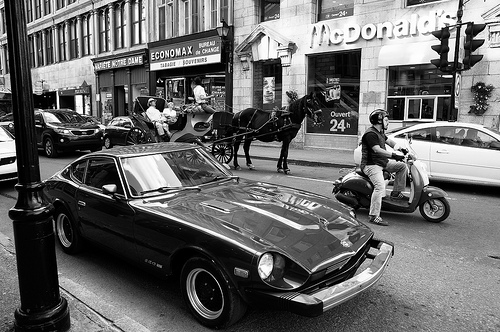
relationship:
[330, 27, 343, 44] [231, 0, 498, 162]
letter on building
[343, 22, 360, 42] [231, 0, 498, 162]
letter on building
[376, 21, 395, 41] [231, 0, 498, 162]
letter on building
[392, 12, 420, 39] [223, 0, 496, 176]
letter on building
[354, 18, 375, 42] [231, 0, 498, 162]
letter on building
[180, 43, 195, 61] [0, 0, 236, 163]
letter on building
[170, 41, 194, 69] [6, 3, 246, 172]
letter on building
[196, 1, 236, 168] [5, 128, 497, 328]
street lamp on road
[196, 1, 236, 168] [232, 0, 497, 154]
street lamp near mcdonalds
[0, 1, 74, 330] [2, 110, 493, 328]
streetlamp on street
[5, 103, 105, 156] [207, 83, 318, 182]
truck behind horse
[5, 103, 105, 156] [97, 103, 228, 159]
truck behind buggy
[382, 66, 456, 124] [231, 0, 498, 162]
windows are in front of building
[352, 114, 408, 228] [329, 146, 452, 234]
man on scooter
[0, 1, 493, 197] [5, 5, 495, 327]
stores are on city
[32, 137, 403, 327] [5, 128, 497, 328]
corvet driving down road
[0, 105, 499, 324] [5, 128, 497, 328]
vehicles are driving down road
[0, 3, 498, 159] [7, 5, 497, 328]
buildings are lining in street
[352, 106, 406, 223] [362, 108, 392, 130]
man wearing helmet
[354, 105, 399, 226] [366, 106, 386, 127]
man wearing helmet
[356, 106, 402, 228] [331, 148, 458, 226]
man riding an scooter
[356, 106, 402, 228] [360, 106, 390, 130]
man wearing helmet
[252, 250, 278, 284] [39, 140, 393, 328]
headlight on car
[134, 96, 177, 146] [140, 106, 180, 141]
man wearing shirt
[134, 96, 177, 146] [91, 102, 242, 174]
man riding a buggy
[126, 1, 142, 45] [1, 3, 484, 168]
window pane on building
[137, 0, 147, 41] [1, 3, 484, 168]
window pane on building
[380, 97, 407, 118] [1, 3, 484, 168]
window pane on building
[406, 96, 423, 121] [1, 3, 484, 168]
window pane on building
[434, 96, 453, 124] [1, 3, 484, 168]
window pane on building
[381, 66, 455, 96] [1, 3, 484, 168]
window pane on building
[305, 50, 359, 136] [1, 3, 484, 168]
window pane on building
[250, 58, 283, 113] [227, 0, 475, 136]
window pane in city building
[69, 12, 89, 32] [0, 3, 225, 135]
window pane in city building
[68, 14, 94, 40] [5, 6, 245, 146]
window pane in city building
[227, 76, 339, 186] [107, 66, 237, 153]
horse pulling carraige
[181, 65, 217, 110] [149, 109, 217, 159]
person in carraige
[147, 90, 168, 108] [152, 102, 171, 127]
hat on man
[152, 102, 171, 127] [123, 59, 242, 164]
man in back of carrage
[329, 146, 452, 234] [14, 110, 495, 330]
scooter in road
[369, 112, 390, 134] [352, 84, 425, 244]
helmet on man man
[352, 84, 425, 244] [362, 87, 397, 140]
man has a head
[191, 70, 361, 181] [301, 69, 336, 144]
horse has a head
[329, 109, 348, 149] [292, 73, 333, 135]
number in front of horse face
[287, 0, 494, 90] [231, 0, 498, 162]
lettering on side of building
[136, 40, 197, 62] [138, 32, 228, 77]
word on sign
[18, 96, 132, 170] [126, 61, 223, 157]
suv behind carraige